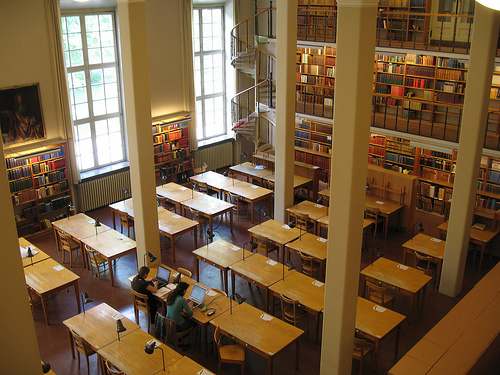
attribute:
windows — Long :
[55, 6, 143, 193]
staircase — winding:
[234, 77, 269, 129]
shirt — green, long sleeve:
[166, 297, 192, 327]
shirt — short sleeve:
[129, 277, 154, 297]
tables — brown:
[51, 176, 415, 337]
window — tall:
[171, 17, 260, 160]